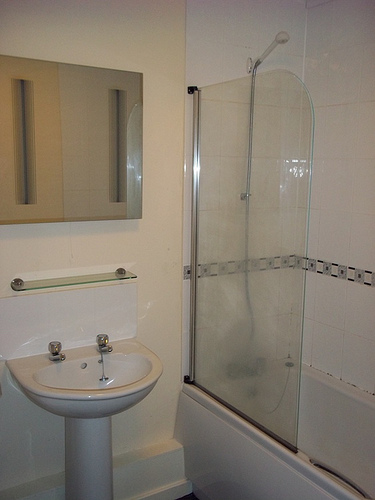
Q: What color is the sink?
A: White.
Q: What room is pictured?
A: Bathroom.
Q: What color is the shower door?
A: Clear.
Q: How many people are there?
A: Zero.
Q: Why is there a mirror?
A: To see.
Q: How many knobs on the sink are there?
A: Two.